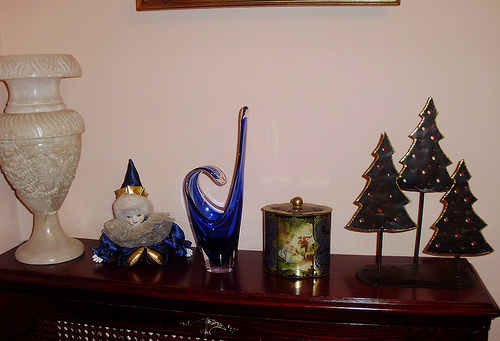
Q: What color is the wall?
A: Off white.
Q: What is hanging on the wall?
A: A framed picture.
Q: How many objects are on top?
A: Five.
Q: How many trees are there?
A: Three.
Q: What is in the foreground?
A: A cabinet.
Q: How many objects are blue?
A: Two.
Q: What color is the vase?
A: White.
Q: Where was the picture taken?
A: Above a mantle.